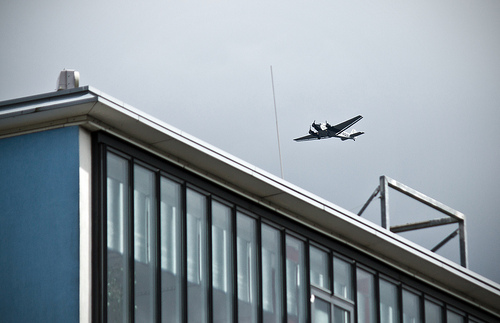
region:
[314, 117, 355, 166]
There is a plane that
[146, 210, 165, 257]
There are windows that are visible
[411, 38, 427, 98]
There is a dark grey sky that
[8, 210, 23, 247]
There is a blue building that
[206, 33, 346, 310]
Jackson Mingus took this photo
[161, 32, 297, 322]
This photo has a great deal of detail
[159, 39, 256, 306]
This photo has a wonderful amount of detail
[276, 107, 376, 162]
white plane in the air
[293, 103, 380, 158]
plane flying in the air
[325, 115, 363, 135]
wing of a plane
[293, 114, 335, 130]
front part of a plane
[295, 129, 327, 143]
wing of a plane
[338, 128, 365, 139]
back end of a plane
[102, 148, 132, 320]
window on side of building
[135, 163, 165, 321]
window on side of building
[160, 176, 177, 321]
window on side of building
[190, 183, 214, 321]
window on side of building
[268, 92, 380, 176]
plane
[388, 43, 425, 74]
white clouds in blue sky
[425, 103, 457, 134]
white clouds in blue sky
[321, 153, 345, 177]
white clouds in blue sky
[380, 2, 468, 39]
white clouds in blue sky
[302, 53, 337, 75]
white clouds in blue sky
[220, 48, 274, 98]
white clouds in blue sky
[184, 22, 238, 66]
white clouds in blue sky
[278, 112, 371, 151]
a plane in the sky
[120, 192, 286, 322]
a building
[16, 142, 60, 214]
a blue wall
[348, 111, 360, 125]
wing of the plane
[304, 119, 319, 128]
the propeller of the plane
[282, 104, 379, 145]
the plane is flying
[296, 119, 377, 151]
the plane is in the sky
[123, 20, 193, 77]
the sky is clear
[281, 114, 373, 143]
a plane in the clear sky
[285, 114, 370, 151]
a plane is flying high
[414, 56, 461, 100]
white clouds in blue sky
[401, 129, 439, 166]
white clouds in blue sky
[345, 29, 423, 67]
white clouds in blue sky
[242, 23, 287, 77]
white clouds in blue sky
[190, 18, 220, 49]
white clouds in blue sky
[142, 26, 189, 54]
white clouds in blue sky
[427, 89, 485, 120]
white clouds in blue sky